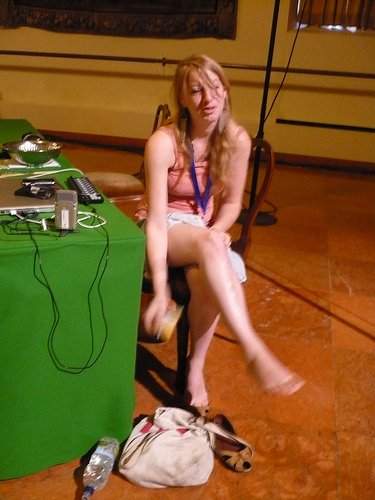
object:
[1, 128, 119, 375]
items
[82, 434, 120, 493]
bottle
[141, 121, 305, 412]
chair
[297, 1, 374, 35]
curtain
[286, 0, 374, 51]
window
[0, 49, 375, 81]
bar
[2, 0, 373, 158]
wall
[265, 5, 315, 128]
cable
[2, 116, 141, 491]
cloth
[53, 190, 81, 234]
speaker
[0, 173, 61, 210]
laptop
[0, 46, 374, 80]
rail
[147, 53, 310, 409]
person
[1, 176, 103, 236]
devices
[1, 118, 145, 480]
table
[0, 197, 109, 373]
cable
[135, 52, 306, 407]
woman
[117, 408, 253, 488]
bag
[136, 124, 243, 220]
tank top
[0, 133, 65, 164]
bowl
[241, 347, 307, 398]
foot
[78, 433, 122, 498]
water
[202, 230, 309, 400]
leg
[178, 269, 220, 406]
leg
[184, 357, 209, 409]
foot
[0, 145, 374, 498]
ground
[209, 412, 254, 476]
shoe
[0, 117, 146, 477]
material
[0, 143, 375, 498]
floor